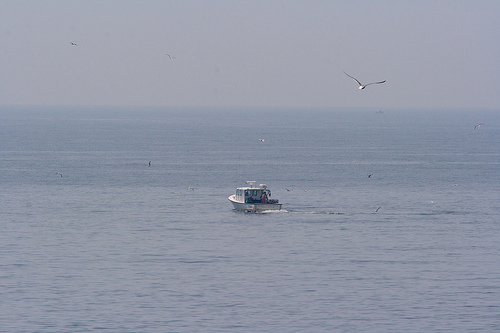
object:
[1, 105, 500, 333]
water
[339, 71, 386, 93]
bird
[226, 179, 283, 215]
boat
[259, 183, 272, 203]
people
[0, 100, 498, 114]
horizon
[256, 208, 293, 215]
waves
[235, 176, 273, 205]
cabin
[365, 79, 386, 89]
wing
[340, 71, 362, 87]
wing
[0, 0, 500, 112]
sky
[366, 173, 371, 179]
spot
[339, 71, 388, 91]
body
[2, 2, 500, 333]
weather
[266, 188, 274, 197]
lines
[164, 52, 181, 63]
birds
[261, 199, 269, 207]
pants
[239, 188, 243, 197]
windows